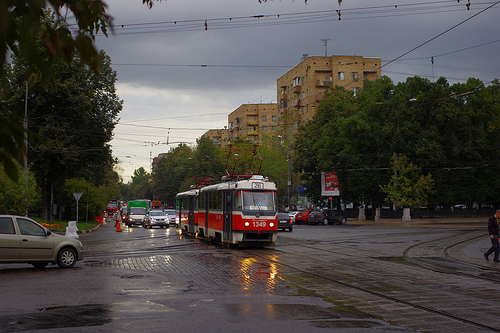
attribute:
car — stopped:
[7, 214, 77, 265]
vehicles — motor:
[131, 191, 179, 235]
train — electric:
[163, 184, 271, 241]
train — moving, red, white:
[170, 170, 282, 255]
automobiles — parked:
[273, 204, 342, 231]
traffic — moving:
[121, 168, 295, 251]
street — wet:
[93, 226, 349, 306]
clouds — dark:
[124, 14, 251, 92]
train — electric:
[172, 174, 288, 252]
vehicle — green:
[122, 194, 149, 232]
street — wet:
[173, 244, 362, 331]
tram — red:
[170, 170, 286, 250]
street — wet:
[113, 224, 193, 256]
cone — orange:
[115, 219, 125, 233]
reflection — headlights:
[236, 255, 286, 318]